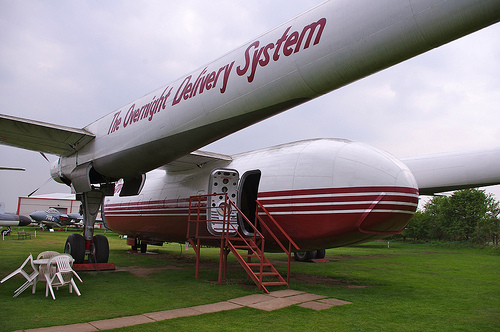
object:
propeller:
[0, 152, 66, 197]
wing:
[0, 109, 92, 156]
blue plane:
[27, 202, 82, 229]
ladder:
[186, 189, 300, 295]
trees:
[406, 184, 498, 254]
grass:
[468, 292, 498, 329]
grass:
[7, 300, 161, 312]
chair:
[45, 252, 84, 301]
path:
[32, 241, 333, 330]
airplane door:
[206, 166, 243, 235]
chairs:
[0, 252, 40, 297]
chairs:
[35, 251, 65, 296]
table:
[32, 257, 75, 294]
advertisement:
[107, 17, 328, 134]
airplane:
[0, 0, 499, 262]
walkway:
[140, 295, 321, 315]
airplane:
[0, 113, 499, 262]